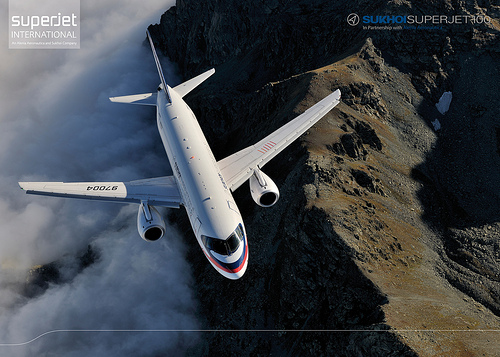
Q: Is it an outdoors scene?
A: Yes, it is outdoors.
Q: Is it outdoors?
A: Yes, it is outdoors.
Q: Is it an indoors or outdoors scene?
A: It is outdoors.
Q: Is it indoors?
A: No, it is outdoors.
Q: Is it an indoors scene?
A: No, it is outdoors.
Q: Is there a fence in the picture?
A: No, there are no fences.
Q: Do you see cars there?
A: No, there are no cars.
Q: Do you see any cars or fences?
A: No, there are no cars or fences.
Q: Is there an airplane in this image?
A: Yes, there is an airplane.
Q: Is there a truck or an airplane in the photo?
A: Yes, there is an airplane.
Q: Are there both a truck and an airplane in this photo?
A: No, there is an airplane but no trucks.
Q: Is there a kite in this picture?
A: No, there are no kites.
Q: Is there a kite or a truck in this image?
A: No, there are no kites or trucks.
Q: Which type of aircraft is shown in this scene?
A: The aircraft is an airplane.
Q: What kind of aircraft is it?
A: The aircraft is an airplane.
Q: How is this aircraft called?
A: This is an airplane.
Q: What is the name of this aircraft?
A: This is an airplane.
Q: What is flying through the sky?
A: The airplane is flying through the sky.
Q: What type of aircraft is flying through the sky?
A: The aircraft is an airplane.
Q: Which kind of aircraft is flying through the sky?
A: The aircraft is an airplane.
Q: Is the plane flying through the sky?
A: Yes, the plane is flying through the sky.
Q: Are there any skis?
A: No, there are no skis.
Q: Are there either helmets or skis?
A: No, there are no skis or helmets.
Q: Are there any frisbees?
A: No, there are no frisbees.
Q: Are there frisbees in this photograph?
A: No, there are no frisbees.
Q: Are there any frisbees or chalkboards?
A: No, there are no frisbees or chalkboards.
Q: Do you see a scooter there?
A: No, there are no scooters.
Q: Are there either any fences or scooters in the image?
A: No, there are no scooters or fences.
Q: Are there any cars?
A: No, there are no cars.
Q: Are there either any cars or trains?
A: No, there are no cars or trains.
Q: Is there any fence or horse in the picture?
A: No, there are no fences or horses.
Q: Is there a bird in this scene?
A: No, there are no birds.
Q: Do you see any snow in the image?
A: Yes, there is snow.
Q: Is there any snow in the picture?
A: Yes, there is snow.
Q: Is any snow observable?
A: Yes, there is snow.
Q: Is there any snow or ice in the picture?
A: Yes, there is snow.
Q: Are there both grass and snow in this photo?
A: No, there is snow but no grass.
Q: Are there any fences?
A: No, there are no fences.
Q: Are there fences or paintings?
A: No, there are no fences or paintings.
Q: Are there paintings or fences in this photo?
A: No, there are no fences or paintings.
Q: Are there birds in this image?
A: No, there are no birds.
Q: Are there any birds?
A: No, there are no birds.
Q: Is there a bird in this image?
A: No, there are no birds.